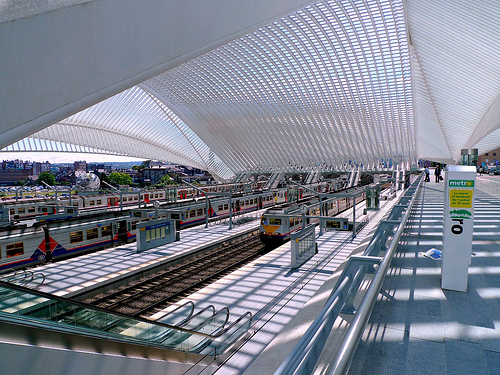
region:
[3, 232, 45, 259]
segment of a train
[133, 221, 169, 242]
segment of a train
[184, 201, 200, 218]
segment of a train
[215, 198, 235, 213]
segment of a train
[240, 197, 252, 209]
segment of a train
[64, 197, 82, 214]
segment of a train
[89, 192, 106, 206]
segment of a train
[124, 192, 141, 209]
segment of a train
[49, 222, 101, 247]
this is a train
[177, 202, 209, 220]
this is a train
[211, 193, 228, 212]
this is a train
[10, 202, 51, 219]
this is a train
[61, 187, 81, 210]
this is a train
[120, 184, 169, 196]
this is a train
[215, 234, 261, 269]
this is a rail way line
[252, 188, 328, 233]
this is a train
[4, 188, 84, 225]
this is a train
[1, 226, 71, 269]
this is a train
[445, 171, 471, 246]
this is a sign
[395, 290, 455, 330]
this is a shadow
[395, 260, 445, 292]
this is a shadow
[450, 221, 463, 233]
this is a letter on a sign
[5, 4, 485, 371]
this is a train station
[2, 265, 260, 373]
green and black escalator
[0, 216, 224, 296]
grey train platform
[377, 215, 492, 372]
shadows on sidewalk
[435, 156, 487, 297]
white box on sidewalk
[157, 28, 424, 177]
white metal grid ceiling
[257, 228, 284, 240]
headlights on front of train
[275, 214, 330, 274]
metal box on platform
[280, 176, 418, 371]
metal rails on side of sidewalk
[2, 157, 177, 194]
city scape in background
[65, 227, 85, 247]
large window on a train at the station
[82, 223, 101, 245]
large window on a train at the station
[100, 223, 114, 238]
large window on a train at the station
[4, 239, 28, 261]
large window on a train at the station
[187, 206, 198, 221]
large window on a train at the station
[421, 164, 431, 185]
person standing at the train station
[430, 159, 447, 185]
person standing at the train station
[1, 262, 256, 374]
pair of escalators at a train station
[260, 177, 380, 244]
train parked at the station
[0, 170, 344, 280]
train parked at the station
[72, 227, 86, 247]
a window on the train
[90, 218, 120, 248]
a window on the train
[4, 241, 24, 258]
a window on a train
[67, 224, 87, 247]
a window on a train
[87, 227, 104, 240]
a window on a train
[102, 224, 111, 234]
a window on a train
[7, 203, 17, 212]
a window on a train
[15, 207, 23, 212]
a window on a train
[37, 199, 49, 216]
a window on a train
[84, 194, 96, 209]
a window on a train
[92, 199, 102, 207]
a window on a train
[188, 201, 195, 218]
a window on a train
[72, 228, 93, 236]
window on the train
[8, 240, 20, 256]
window on the train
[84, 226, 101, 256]
window on the train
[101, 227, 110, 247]
window on the train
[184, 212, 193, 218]
window on the train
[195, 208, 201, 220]
window on the train